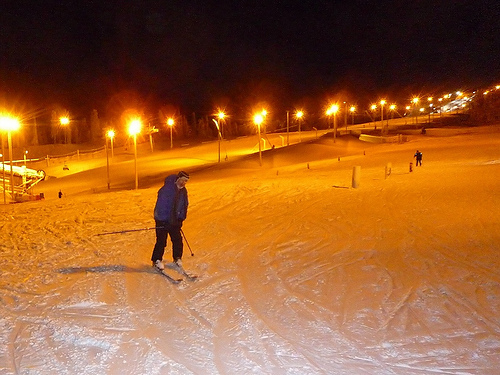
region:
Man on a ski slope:
[123, 161, 213, 283]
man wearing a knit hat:
[166, 168, 191, 193]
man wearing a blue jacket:
[152, 171, 195, 228]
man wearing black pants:
[150, 215, 185, 262]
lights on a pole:
[120, 108, 147, 143]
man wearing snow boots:
[153, 253, 186, 277]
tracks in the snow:
[266, 189, 436, 291]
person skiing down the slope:
[406, 138, 430, 174]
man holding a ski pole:
[91, 218, 173, 244]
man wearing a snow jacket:
[141, 165, 196, 235]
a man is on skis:
[153, 168, 200, 286]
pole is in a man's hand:
[177, 227, 194, 260]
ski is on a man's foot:
[153, 262, 179, 283]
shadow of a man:
[59, 265, 158, 275]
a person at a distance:
[413, 148, 424, 166]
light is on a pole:
[126, 118, 143, 135]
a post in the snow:
[351, 163, 361, 189]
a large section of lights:
[202, 92, 474, 132]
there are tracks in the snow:
[2, 206, 147, 373]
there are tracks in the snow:
[205, 243, 498, 373]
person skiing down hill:
[96, 167, 209, 290]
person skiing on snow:
[65, 174, 205, 303]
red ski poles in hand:
[91, 225, 157, 241]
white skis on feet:
[152, 258, 201, 288]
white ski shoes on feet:
[145, 252, 187, 271]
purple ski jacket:
[145, 184, 190, 218]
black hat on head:
[179, 168, 186, 178]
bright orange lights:
[4, 90, 229, 157]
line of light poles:
[107, 95, 422, 156]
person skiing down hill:
[402, 142, 434, 176]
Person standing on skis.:
[144, 250, 201, 279]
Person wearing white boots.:
[153, 261, 201, 272]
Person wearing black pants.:
[154, 229, 182, 251]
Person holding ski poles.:
[145, 225, 192, 242]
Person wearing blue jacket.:
[155, 195, 172, 212]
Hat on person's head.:
[173, 170, 195, 187]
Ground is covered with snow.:
[300, 304, 385, 356]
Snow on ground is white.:
[171, 304, 271, 354]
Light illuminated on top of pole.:
[249, 112, 267, 133]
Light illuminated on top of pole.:
[123, 115, 147, 140]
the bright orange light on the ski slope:
[3, 111, 22, 138]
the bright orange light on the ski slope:
[57, 115, 69, 126]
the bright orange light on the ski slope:
[104, 128, 116, 141]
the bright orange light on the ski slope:
[127, 116, 144, 138]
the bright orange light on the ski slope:
[165, 117, 177, 128]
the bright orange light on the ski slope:
[217, 107, 227, 121]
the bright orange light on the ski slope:
[250, 113, 263, 126]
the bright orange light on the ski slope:
[295, 109, 305, 119]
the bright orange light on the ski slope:
[328, 101, 340, 114]